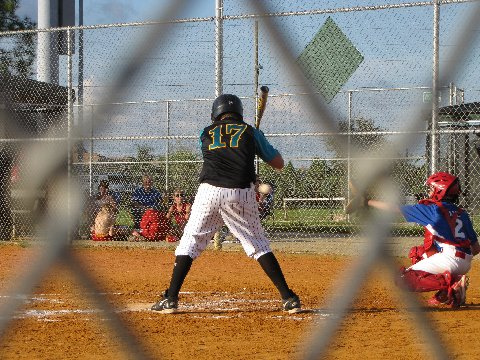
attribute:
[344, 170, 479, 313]
catcher — hind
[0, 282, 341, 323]
chalk outlines — white, of box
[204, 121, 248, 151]
number — green, seventeen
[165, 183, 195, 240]
spectator — watching baseball game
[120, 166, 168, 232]
spectator — watching baseball game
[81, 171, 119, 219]
spectator — watching baseball game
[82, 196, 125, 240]
spectator — watching baseball game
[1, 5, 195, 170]
fence — silver, metal, chain link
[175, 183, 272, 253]
pants — striped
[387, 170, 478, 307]
player — white, baseball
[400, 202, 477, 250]
jersey — blue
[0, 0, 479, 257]
fencing — metal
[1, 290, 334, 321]
white line — painted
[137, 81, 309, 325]
person — at bat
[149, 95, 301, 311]
player — white, baseball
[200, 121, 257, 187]
jersey — black 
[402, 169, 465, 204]
mask — red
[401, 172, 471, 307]
catcher — catchers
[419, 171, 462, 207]
helmet — red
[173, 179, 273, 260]
pants — striped, black, white